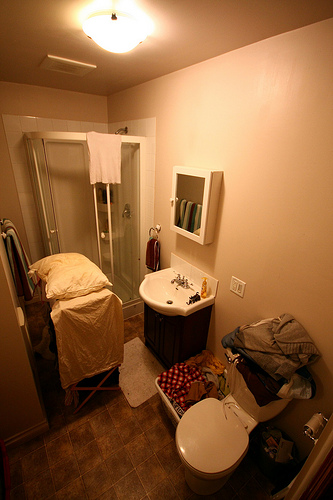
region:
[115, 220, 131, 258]
Bathroom glass door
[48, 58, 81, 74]
Ventilation in the ceiling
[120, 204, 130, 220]
The metallic water handle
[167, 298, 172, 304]
The basin drain hole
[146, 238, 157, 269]
Hanging hand towel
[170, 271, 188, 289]
Metallic taps on the basin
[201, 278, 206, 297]
A liquid soap bottle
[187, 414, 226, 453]
A toilet cover closed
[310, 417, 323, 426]
A white toilet roll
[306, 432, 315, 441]
Metallic mounting for toilet paper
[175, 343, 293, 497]
A white toilet with silver flusher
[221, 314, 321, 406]
Pile of clothes on the back of the toilet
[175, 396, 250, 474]
A white closed toilet seat lid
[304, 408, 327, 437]
A brown empty toilet paper roll on a holder.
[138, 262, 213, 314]
A white porecelain sink.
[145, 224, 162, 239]
Silver round towel holder to the left of the sink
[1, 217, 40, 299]
A colorful striped towel hanging on the wall behind a pillow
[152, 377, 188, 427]
White plastic laundry basket holding clothes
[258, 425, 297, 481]
A full dark trashcan by the toilet on the floor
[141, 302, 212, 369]
A dark cherry wood bathroom cabinet under the sink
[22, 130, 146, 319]
A tall glass shower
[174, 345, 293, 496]
A white toilet with the seat down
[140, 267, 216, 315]
A white porcelain sink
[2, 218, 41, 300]
A striped colorful towel hanging behind a pillow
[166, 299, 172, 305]
Silver drain in a white sink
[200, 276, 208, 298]
Yellow pump bottle of soap on the sink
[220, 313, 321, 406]
A pile of clothes stacked up on the back of the toilet.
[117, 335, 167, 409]
A light colored rug on the floor by the sink.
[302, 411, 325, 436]
A brown cardboard toilet paper roll on the wall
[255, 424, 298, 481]
A black trashcan with trash in it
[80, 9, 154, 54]
ceiling light fixture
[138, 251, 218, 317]
porcelain bathroom sink on vanity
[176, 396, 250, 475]
white toilet seat lid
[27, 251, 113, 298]
white bed pillow with no cover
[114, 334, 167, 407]
white, slightly dirty bath rug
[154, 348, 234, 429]
laundry hamper full of clothing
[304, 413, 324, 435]
empty roll of toilet paper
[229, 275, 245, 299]
white light switch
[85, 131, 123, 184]
white towel over shower door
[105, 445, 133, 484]
terra cotta bath tile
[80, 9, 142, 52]
a domed light in the ceiling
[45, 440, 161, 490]
brown tile on the floor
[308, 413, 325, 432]
cardboard toilet paper roll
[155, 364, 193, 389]
red and black plaid garment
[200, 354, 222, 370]
yellow garment in basket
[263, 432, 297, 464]
trash in the trash can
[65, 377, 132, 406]
wooden drying rack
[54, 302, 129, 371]
white sheet on drying rack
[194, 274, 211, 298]
bottle of yellow handsoap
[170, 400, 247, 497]
white toilet in a bathroom